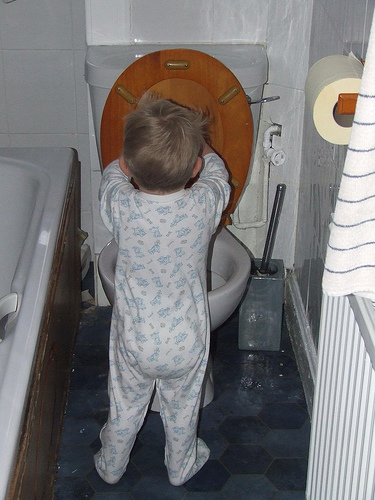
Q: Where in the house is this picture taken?
A: Bathroom.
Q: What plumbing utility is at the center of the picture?
A: Toilet.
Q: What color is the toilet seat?
A: Brown.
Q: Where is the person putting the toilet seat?
A: Up.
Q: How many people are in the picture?
A: One.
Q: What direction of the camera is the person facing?
A: Away.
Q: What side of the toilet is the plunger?
A: Right.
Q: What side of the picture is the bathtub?
A: Left.